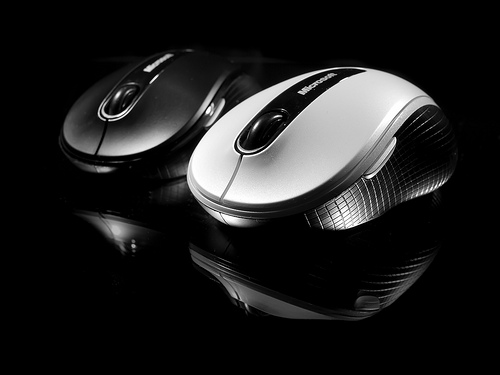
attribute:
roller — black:
[242, 108, 288, 145]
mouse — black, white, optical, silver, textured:
[184, 51, 460, 236]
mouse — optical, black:
[63, 43, 261, 174]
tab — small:
[361, 134, 408, 183]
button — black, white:
[365, 136, 401, 181]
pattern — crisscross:
[297, 97, 464, 229]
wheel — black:
[249, 113, 286, 142]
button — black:
[201, 99, 229, 127]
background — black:
[0, 2, 496, 370]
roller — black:
[110, 84, 138, 112]